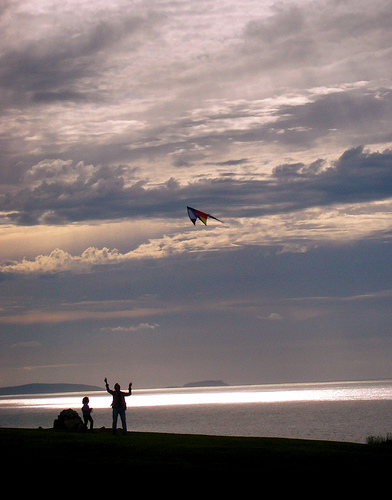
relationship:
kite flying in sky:
[181, 206, 221, 231] [1, 2, 390, 385]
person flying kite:
[103, 376, 134, 435] [181, 206, 221, 231]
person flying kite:
[81, 394, 94, 430] [181, 206, 221, 231]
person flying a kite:
[103, 376, 134, 435] [181, 206, 221, 231]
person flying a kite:
[81, 394, 94, 430] [181, 206, 221, 231]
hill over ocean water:
[2, 423, 389, 499] [1, 379, 391, 444]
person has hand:
[103, 376, 134, 435] [102, 378, 110, 384]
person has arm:
[103, 376, 134, 435] [105, 379, 115, 395]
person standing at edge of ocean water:
[103, 376, 134, 435] [1, 379, 391, 444]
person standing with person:
[103, 376, 134, 435] [81, 394, 94, 430]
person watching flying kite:
[81, 394, 94, 430] [181, 206, 221, 231]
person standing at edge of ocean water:
[81, 394, 94, 430] [1, 379, 391, 444]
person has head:
[103, 376, 134, 435] [115, 384, 121, 394]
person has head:
[103, 376, 134, 435] [81, 397, 92, 406]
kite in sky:
[181, 206, 221, 231] [1, 2, 390, 385]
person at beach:
[103, 376, 134, 435] [2, 421, 391, 451]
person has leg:
[103, 376, 134, 435] [121, 409, 129, 429]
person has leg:
[103, 376, 134, 435] [112, 411, 118, 430]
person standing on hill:
[103, 376, 134, 435] [2, 423, 389, 499]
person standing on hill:
[81, 394, 94, 430] [2, 423, 389, 499]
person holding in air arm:
[103, 376, 134, 435] [105, 379, 115, 395]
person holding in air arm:
[103, 376, 134, 435] [122, 382, 135, 396]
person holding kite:
[81, 394, 94, 430] [181, 206, 221, 231]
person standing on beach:
[103, 376, 134, 435] [2, 421, 391, 451]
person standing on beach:
[81, 394, 94, 430] [2, 421, 391, 451]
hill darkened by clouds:
[2, 423, 389, 499] [2, 2, 391, 384]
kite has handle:
[181, 206, 221, 231] [104, 372, 110, 381]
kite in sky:
[181, 206, 221, 231] [95, 81, 207, 117]